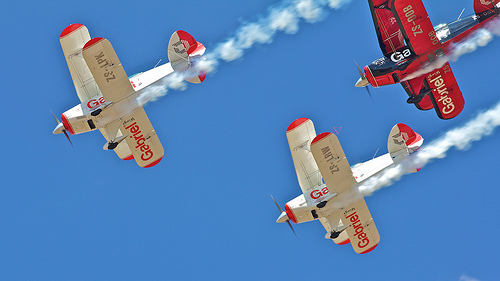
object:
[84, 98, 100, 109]
writing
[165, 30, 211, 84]
tail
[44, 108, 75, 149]
propeller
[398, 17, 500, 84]
smoke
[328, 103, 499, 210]
smoke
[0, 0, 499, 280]
sky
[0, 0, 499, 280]
blue sky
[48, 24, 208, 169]
body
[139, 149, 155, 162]
writing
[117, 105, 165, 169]
wing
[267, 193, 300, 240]
propeller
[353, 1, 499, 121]
plane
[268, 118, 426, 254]
branding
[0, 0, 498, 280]
air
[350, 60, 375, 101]
propeller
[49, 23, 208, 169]
airplane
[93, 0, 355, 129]
smoke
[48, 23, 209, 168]
branding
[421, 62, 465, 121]
wing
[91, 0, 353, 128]
contrails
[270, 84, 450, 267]
plane